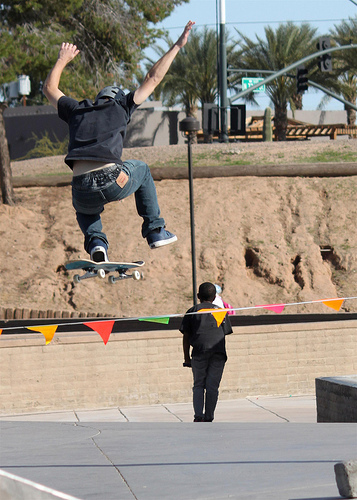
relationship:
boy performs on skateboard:
[45, 9, 194, 260] [35, 251, 181, 308]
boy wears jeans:
[45, 9, 194, 260] [71, 159, 179, 261]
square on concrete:
[118, 405, 182, 421] [0, 394, 357, 498]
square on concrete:
[76, 407, 126, 420] [8, 413, 316, 496]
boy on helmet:
[41, 20, 195, 261] [95, 82, 127, 98]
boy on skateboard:
[41, 20, 195, 261] [64, 257, 146, 281]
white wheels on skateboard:
[72, 269, 141, 281] [61, 259, 145, 281]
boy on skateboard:
[45, 9, 194, 260] [60, 256, 147, 285]